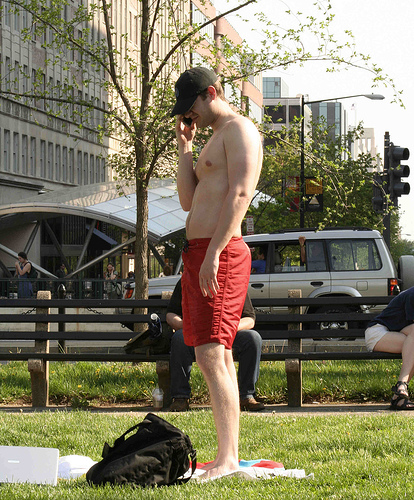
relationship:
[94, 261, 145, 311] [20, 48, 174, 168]
woman in front of building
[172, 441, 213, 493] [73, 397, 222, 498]
strap on bag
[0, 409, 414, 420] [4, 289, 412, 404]
path under bench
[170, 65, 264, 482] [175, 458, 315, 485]
man standing on towel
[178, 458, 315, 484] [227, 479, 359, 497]
towel lying on grass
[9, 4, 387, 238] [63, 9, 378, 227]
trees beginning to grow leaves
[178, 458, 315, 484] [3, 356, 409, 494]
towel on grass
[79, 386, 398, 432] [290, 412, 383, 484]
path by grass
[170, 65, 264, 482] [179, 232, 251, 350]
man in shorts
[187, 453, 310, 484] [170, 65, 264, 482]
towel under man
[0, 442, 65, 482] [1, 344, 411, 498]
laptop on grass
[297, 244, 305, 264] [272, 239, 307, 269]
arm outside window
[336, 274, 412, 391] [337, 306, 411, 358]
person wearing white shorts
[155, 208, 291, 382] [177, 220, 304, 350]
man wearing shorts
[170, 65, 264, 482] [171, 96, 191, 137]
man on cellphone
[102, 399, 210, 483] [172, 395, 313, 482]
bag by feet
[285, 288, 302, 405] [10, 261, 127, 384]
support for bench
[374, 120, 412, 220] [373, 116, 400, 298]
stoplight on pole